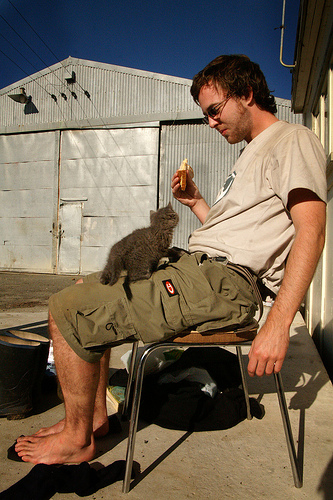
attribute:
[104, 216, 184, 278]
kitty — sitting, brown, cute, little, young, grey, small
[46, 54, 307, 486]
man — barefoot, eating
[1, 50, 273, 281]
building — grey, metal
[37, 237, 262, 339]
shorts — cargo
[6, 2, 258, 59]
sky — blue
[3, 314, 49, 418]
boot — black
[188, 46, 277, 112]
hair — dark, brown